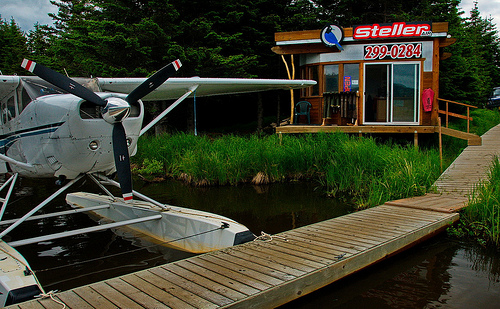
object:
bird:
[324, 24, 345, 51]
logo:
[319, 24, 345, 53]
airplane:
[0, 57, 317, 309]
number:
[365, 43, 422, 59]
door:
[360, 60, 421, 127]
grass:
[140, 129, 447, 206]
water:
[0, 191, 498, 306]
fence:
[436, 97, 478, 133]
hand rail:
[436, 98, 477, 133]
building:
[270, 21, 481, 145]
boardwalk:
[0, 122, 499, 308]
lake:
[2, 177, 499, 309]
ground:
[409, 145, 499, 226]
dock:
[1, 121, 498, 307]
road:
[447, 129, 500, 191]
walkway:
[318, 213, 457, 248]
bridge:
[1, 202, 463, 308]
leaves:
[28, 13, 278, 74]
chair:
[294, 101, 312, 125]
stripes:
[172, 59, 183, 71]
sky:
[0, 0, 55, 32]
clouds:
[0, 0, 59, 30]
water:
[170, 183, 344, 223]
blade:
[21, 59, 183, 204]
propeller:
[17, 58, 183, 205]